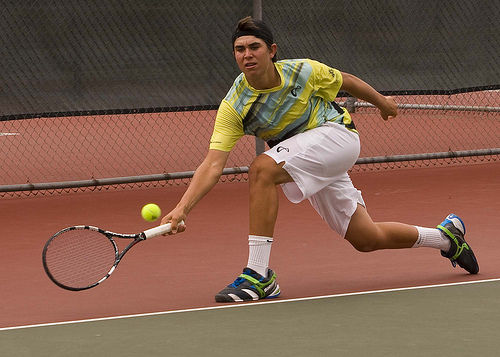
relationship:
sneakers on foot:
[214, 263, 279, 306] [213, 265, 279, 306]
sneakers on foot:
[434, 213, 483, 275] [432, 211, 479, 273]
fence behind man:
[0, 0, 499, 201] [158, 14, 490, 304]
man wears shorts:
[158, 14, 490, 304] [261, 121, 366, 240]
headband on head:
[234, 22, 275, 43] [231, 14, 279, 84]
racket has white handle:
[40, 225, 187, 291] [140, 215, 183, 240]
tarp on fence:
[2, 1, 497, 122] [3, 1, 499, 201]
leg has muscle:
[198, 152, 479, 307] [264, 175, 280, 232]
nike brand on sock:
[264, 233, 274, 243] [246, 235, 273, 278]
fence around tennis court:
[3, 1, 499, 201] [2, 87, 496, 354]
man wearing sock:
[160, 20, 478, 303] [243, 218, 286, 284]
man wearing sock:
[160, 20, 478, 303] [407, 208, 470, 252]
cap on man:
[230, 18, 274, 46] [158, 14, 490, 304]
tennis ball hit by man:
[135, 199, 165, 226] [158, 14, 490, 304]